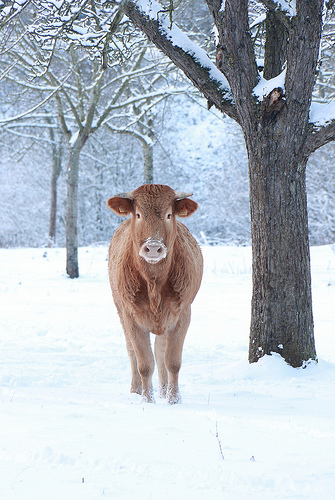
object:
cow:
[94, 182, 217, 408]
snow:
[5, 247, 334, 447]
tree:
[121, 0, 334, 371]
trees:
[19, 0, 126, 280]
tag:
[115, 204, 131, 218]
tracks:
[40, 309, 189, 408]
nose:
[141, 243, 167, 260]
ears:
[101, 193, 134, 221]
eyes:
[132, 206, 143, 227]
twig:
[36, 248, 55, 262]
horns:
[113, 189, 136, 202]